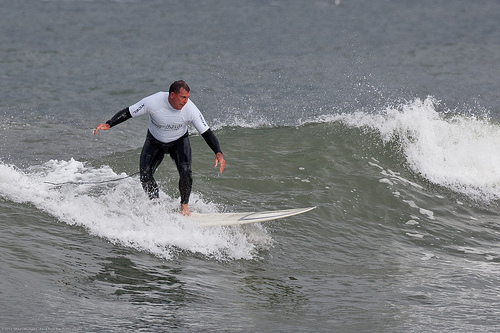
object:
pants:
[139, 131, 193, 204]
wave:
[0, 103, 497, 256]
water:
[3, 2, 496, 329]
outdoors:
[4, 7, 497, 328]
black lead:
[41, 172, 140, 186]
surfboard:
[154, 206, 318, 227]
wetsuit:
[103, 91, 222, 205]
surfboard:
[179, 205, 317, 227]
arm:
[188, 111, 223, 155]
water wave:
[245, 91, 496, 214]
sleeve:
[191, 114, 224, 155]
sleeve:
[105, 97, 148, 128]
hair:
[169, 78, 191, 94]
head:
[168, 80, 190, 109]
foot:
[177, 205, 191, 219]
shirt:
[129, 91, 211, 143]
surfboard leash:
[42, 171, 140, 185]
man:
[93, 80, 225, 217]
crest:
[212, 96, 432, 146]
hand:
[210, 151, 228, 178]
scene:
[2, 5, 498, 328]